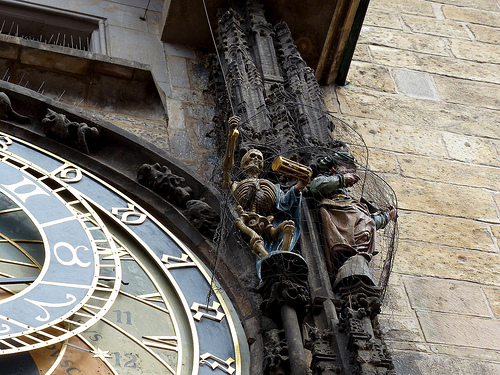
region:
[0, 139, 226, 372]
this is a clock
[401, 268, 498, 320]
a brick on the wall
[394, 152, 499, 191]
a brick on the wall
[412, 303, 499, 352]
a brick on the wall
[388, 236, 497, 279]
a brick on the wall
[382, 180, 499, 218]
a brick on the wall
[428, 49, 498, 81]
a brick on the wall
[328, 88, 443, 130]
a brick on the wall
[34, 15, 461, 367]
this is a decoration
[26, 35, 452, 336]
this is on the side of a building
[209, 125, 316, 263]
this is a skeleton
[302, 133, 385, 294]
this is a man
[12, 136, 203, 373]
the clock is very large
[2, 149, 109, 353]
this clock is blue and white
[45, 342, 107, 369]
this part of the clock is orange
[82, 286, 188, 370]
this part of the clock is silver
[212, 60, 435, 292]
there are statues on the post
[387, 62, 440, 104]
light grey brick on tan wall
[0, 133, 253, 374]
part of large clock on face of building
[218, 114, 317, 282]
skeleton on pillar in front of brick building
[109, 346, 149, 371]
number twelve on face of clock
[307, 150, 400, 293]
statue in brown clothing on face of wall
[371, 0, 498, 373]
brick wall on face of building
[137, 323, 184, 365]
gold roman numeral six on clock face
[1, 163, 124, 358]
gold symbols on small face of clock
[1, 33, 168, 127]
brick ledge above clock on face of building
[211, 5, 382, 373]
black pillars holding two figures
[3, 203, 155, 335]
this is a clock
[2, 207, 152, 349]
the clock is big in size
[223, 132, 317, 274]
this is a skeleton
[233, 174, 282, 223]
the skeleton is on the wall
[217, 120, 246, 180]
this is the hand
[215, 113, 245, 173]
the hand is raised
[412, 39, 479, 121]
this is the wall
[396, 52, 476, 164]
the wall is stony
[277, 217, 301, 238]
this is the knee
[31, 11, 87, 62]
the window is open